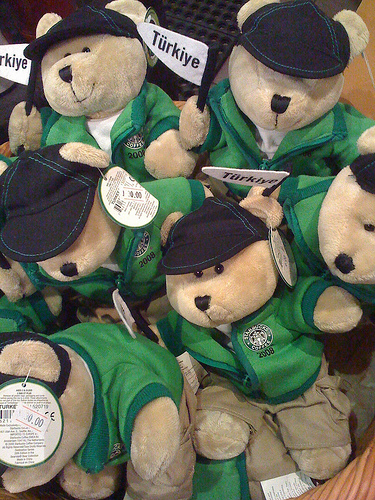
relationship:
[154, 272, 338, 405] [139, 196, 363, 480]
green jacket on tan bear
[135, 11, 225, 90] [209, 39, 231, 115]
white flag on black pole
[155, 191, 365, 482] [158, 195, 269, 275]
animal wearing hat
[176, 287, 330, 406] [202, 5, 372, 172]
jacket on animal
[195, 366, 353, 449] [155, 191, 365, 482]
pants on animal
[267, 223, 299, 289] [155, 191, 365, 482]
tag hanging from animal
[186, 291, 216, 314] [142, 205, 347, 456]
nose on animal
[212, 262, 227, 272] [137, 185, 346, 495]
eyes on stuffed animal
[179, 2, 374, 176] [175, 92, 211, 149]
bear has paws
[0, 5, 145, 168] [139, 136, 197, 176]
bear has paws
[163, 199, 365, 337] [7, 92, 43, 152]
bear has paws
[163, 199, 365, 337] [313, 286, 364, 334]
bear has paws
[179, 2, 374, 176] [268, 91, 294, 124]
bear has nose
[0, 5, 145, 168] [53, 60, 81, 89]
bear has nose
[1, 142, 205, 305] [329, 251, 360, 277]
bear has nose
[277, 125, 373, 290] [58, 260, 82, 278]
bear has nose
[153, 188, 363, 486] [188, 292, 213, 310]
bear has nose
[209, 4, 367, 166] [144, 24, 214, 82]
bear holds flag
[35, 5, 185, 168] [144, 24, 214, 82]
bear holds flag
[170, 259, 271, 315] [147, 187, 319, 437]
face in teddy bear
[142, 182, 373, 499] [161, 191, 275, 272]
stuffed animal wears hat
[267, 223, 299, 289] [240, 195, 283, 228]
tag on ear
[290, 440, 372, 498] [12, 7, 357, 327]
basket holding bears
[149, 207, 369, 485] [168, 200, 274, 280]
bear wearing hat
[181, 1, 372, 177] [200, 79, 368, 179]
teddy bear with jacket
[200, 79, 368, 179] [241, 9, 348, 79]
jacket and hat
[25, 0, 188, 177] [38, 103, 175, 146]
teddy bear with jacket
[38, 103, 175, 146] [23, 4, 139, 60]
jacket and hat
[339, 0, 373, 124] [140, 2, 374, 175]
table near bear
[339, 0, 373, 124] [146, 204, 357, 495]
table near bear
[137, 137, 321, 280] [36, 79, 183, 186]
shirt worn under jacket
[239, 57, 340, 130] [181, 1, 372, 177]
face of teddy bear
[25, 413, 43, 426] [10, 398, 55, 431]
numbers on pricetag